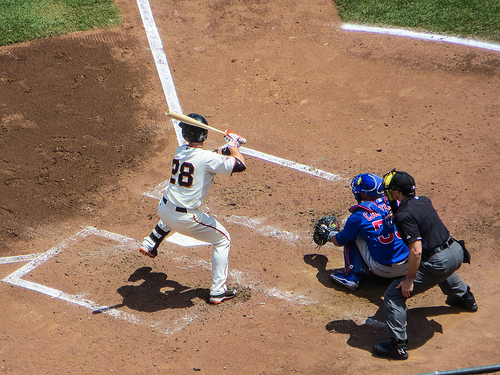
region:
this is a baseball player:
[122, 112, 236, 312]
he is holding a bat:
[171, 114, 243, 146]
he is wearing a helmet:
[182, 131, 200, 138]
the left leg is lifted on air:
[128, 222, 177, 252]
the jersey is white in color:
[163, 157, 205, 221]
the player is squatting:
[321, 200, 389, 281]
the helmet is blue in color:
[350, 175, 375, 194]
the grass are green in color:
[1, 0, 100, 32]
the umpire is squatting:
[403, 225, 470, 297]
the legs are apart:
[138, 239, 232, 283]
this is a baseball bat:
[160, 100, 250, 143]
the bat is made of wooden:
[168, 107, 195, 127]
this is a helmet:
[178, 115, 209, 141]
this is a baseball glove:
[311, 205, 333, 250]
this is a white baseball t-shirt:
[170, 185, 190, 197]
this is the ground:
[24, 104, 81, 201]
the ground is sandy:
[32, 98, 127, 183]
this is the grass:
[3, 5, 98, 16]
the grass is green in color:
[388, 3, 483, 25]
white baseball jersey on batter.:
[170, 170, 200, 215]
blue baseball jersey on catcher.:
[358, 206, 395, 252]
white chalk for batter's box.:
[275, 149, 322, 181]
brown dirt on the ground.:
[330, 105, 434, 145]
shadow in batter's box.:
[122, 269, 188, 305]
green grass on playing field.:
[17, 5, 84, 21]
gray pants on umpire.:
[436, 255, 464, 275]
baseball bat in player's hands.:
[161, 108, 233, 136]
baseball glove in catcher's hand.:
[315, 214, 333, 246]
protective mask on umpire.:
[387, 174, 395, 206]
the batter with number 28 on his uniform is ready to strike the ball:
[137, 107, 249, 308]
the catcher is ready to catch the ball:
[315, 172, 413, 292]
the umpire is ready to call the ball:
[370, 167, 478, 360]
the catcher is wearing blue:
[313, 172, 417, 292]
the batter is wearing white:
[137, 108, 244, 302]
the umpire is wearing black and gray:
[371, 169, 478, 360]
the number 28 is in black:
[168, 157, 194, 191]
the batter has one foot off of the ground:
[136, 107, 243, 304]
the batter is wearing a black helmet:
[179, 111, 207, 141]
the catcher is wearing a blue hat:
[346, 170, 386, 198]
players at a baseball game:
[20, 41, 499, 362]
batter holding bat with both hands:
[145, 95, 250, 165]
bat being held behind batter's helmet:
[151, 105, 249, 151]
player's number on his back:
[156, 150, 199, 196]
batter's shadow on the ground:
[85, 260, 225, 328]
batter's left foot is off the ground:
[115, 198, 177, 285]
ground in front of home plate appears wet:
[0, 40, 212, 255]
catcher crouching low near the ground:
[300, 150, 400, 290]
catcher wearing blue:
[327, 162, 402, 264]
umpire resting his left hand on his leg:
[375, 158, 444, 320]